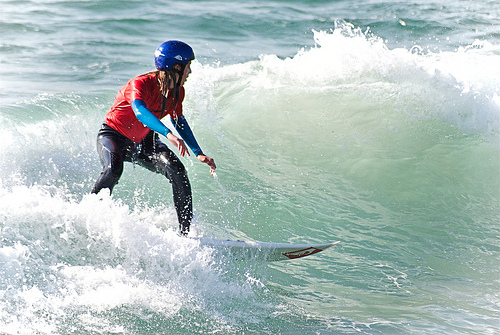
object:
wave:
[1, 19, 498, 332]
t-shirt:
[108, 67, 185, 140]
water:
[0, 1, 492, 106]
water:
[3, 87, 251, 216]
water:
[4, 178, 228, 327]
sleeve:
[133, 102, 173, 144]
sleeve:
[172, 105, 202, 159]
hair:
[156, 60, 179, 101]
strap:
[163, 64, 187, 88]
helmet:
[151, 35, 192, 70]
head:
[144, 31, 198, 92]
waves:
[27, 180, 140, 263]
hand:
[197, 151, 219, 176]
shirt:
[83, 60, 228, 155]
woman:
[49, 41, 294, 240]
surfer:
[31, 37, 330, 282]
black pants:
[93, 116, 210, 236]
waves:
[333, 118, 440, 158]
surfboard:
[192, 228, 349, 267]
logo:
[279, 246, 322, 260]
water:
[212, 181, 266, 251]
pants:
[91, 126, 192, 232]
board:
[187, 233, 338, 264]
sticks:
[160, 65, 187, 107]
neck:
[152, 66, 189, 102]